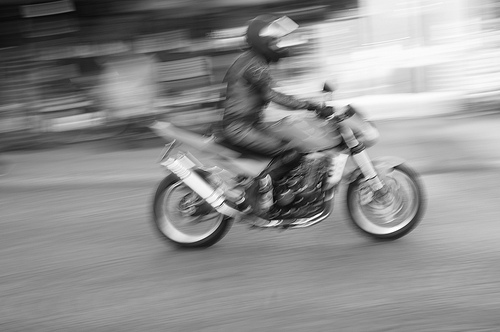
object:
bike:
[153, 78, 425, 248]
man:
[211, 13, 332, 214]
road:
[1, 137, 499, 331]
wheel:
[154, 170, 232, 248]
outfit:
[221, 50, 334, 210]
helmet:
[247, 13, 309, 62]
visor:
[261, 14, 299, 41]